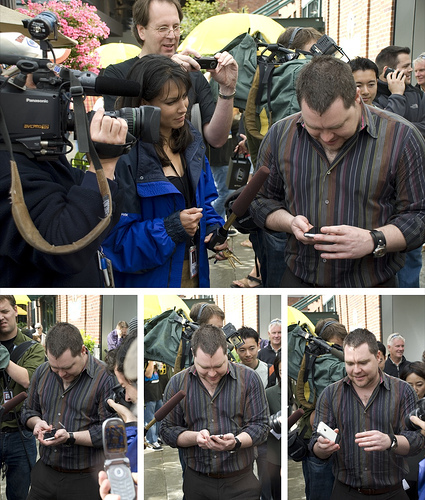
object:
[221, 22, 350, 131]
cameraman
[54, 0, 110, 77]
flowers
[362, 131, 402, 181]
ground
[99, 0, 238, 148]
man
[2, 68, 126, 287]
man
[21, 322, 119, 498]
man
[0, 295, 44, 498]
man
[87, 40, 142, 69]
yellow umbrella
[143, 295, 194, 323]
yellow umbrella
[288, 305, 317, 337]
yellow umbrella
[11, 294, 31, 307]
yellow umbrella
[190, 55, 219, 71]
camera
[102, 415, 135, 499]
cellphone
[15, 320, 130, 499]
man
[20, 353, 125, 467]
striped shirt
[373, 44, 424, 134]
man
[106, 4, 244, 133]
man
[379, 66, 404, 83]
cellphone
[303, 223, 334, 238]
phone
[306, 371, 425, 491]
striped shirt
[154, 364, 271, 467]
striped shirt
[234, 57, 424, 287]
man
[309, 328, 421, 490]
man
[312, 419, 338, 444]
iphone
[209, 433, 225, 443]
iphone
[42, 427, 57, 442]
iphone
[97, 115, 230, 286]
coat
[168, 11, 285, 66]
umbrellas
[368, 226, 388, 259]
wrist watch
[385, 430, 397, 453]
wrist watch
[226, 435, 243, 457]
wrist watch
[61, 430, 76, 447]
wrist watch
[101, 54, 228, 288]
woman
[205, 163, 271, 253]
microphone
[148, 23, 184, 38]
eyeglasses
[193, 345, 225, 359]
hairline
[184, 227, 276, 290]
ground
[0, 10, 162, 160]
camera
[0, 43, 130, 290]
photographer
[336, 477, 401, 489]
belt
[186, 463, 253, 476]
belt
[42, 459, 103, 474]
belt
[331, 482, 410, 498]
pants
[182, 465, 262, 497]
pants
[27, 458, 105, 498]
pants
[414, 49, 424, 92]
man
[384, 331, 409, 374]
man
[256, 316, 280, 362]
man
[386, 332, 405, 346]
hair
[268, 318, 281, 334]
hair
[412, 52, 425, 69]
hair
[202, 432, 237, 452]
hands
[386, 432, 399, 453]
band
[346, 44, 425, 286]
gathering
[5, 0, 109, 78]
tree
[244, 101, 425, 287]
shirt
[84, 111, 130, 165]
hand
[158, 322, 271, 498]
he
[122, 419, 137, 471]
jacket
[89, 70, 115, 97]
part